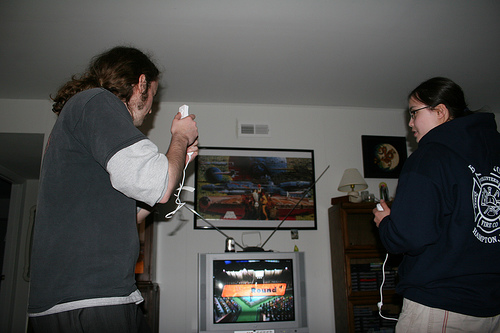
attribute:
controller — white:
[178, 104, 189, 119]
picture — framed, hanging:
[195, 146, 317, 230]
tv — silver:
[198, 253, 308, 332]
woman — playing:
[371, 75, 500, 332]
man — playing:
[26, 47, 198, 333]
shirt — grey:
[28, 85, 149, 314]